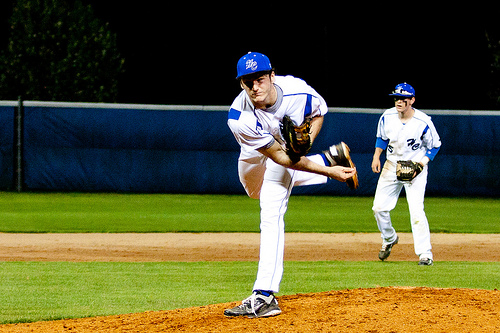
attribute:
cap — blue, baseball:
[236, 52, 273, 79]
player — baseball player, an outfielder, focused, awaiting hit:
[370, 82, 440, 266]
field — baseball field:
[0, 101, 498, 332]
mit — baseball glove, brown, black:
[395, 160, 423, 182]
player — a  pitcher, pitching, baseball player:
[223, 52, 357, 319]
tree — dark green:
[1, 0, 128, 103]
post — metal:
[15, 93, 24, 192]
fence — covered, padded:
[0, 101, 496, 197]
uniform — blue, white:
[372, 107, 441, 256]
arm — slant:
[229, 120, 333, 173]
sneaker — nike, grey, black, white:
[224, 293, 280, 317]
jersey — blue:
[227, 75, 329, 157]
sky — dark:
[1, 0, 497, 108]